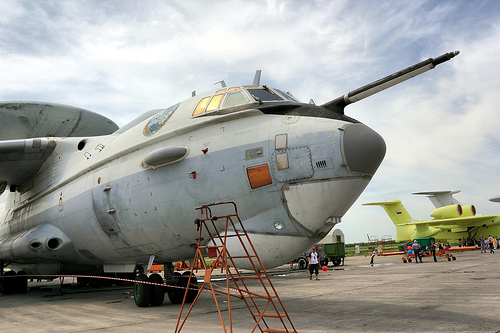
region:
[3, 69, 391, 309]
large airplane on display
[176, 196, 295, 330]
ladder going up to airplane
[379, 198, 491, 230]
yellow airplane on display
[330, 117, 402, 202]
nose of the airplane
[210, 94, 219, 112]
window on side of airplane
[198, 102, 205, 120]
window on side of airplane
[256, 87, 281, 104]
window on side of airplane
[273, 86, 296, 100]
window on side of airplane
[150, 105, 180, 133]
window on side of airplane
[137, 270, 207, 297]
wheels on front of plane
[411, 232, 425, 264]
This is a person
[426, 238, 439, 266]
This is a person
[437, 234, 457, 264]
This is a person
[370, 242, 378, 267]
This is a person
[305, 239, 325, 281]
This is a person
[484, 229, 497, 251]
This is a person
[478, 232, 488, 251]
This is a person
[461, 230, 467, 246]
This is a person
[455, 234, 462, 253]
This is a person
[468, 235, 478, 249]
This is a person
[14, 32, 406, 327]
A large grey aircraft on a runway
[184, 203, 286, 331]
A small orange stepladder to get up to the plane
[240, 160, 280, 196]
A small orange hatch by the plane's nose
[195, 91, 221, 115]
The lights are on inside of the plane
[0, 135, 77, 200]
A grey and white wing of the plane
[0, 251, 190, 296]
A thin red and white rope around the plane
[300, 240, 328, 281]
A man in a white shirt behind the plane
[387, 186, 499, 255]
An enormous green plane by the people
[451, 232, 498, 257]
A crowd by the large green plane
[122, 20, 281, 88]
Wispy white clouds in the sky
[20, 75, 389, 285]
This is a big plane.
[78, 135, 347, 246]
This plane is gray and light blue.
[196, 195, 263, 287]
This is a step ladder.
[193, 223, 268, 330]
The ladder is orange.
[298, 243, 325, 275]
This man is wearing a white shirt.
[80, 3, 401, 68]
the sky is blue and white.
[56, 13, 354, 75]
the weather is partly cloudy.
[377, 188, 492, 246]
These planes are lime green.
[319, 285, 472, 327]
This runway is made of concrete.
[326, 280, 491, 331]
The runway is gray.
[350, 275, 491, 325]
tarmac at an airport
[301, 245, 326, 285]
man walking on tarmac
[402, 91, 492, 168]
a cloudy sky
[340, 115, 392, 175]
nose of an airplane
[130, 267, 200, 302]
four wheels of an aircraft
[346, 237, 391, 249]
area of grass and trees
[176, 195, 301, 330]
orange utility ladder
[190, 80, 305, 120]
cockpit of a plane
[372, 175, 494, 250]
planes lined up on runway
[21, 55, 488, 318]
cargo plane awaits servicing